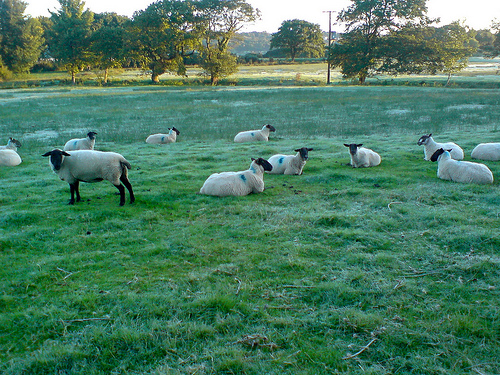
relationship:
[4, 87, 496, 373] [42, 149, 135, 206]
an area with sheep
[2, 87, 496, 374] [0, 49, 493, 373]
grass in field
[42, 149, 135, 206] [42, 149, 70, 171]
sheep has face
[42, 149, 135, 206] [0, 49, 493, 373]
sheep in a field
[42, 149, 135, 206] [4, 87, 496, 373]
sheep in an an area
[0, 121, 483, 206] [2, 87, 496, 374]
sheep laying on grass